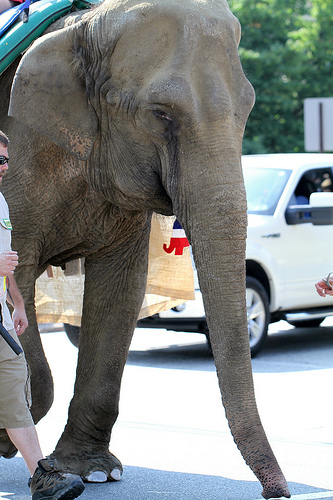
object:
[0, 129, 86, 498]
man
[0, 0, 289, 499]
elephant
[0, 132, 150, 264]
wrinkles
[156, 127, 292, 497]
trunk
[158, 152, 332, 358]
car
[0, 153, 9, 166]
sunglasses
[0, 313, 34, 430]
shorts